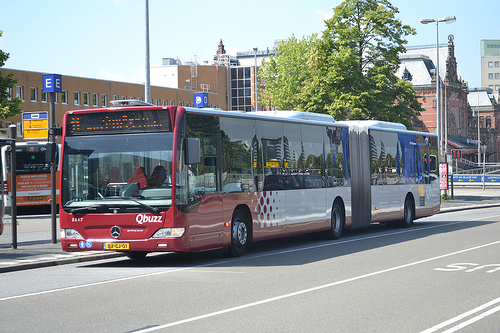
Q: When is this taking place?
A: Daytime.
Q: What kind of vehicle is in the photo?
A: Bus.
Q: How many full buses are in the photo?
A: One.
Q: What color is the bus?
A: Red, white and blue.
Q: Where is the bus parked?
A: Street.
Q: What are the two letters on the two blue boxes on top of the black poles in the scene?
A: E and O.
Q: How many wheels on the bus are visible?
A: Three.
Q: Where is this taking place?
A: In a city.